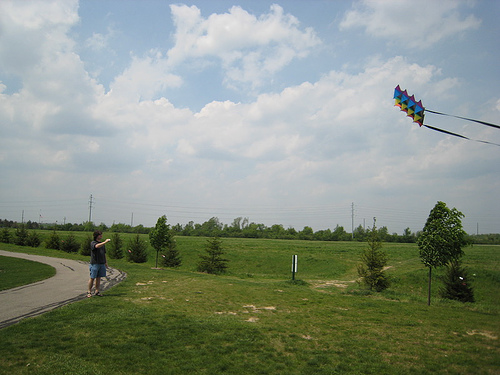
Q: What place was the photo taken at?
A: It was taken at the field.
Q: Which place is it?
A: It is a field.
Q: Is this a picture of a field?
A: Yes, it is showing a field.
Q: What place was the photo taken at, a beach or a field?
A: It was taken at a field.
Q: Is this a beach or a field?
A: It is a field.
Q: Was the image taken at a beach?
A: No, the picture was taken in a field.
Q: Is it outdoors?
A: Yes, it is outdoors.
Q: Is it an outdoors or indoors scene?
A: It is outdoors.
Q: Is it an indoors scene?
A: No, it is outdoors.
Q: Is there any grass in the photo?
A: Yes, there is grass.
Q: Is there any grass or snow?
A: Yes, there is grass.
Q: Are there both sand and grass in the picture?
A: No, there is grass but no sand.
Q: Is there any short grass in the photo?
A: Yes, there is short grass.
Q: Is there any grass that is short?
A: Yes, there is grass that is short.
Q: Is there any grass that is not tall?
A: Yes, there is short grass.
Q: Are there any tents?
A: No, there are no tents.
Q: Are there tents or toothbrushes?
A: No, there are no tents or toothbrushes.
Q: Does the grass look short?
A: Yes, the grass is short.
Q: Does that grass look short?
A: Yes, the grass is short.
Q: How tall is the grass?
A: The grass is short.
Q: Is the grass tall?
A: No, the grass is short.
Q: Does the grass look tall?
A: No, the grass is short.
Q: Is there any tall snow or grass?
A: No, there is grass but it is short.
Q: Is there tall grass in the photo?
A: No, there is grass but it is short.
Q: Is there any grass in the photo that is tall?
A: No, there is grass but it is short.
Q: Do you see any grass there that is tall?
A: No, there is grass but it is short.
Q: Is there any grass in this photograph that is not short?
A: No, there is grass but it is short.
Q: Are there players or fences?
A: No, there are no fences or players.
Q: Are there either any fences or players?
A: No, there are no fences or players.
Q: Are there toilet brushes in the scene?
A: No, there are no toilet brushes.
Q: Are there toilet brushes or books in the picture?
A: No, there are no toilet brushes or books.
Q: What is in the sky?
A: The clouds are in the sky.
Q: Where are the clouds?
A: The clouds are in the sky.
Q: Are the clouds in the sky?
A: Yes, the clouds are in the sky.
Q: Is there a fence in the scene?
A: No, there are no fences.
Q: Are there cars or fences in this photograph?
A: No, there are no fences or cars.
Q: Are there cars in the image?
A: No, there are no cars.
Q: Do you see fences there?
A: No, there are no fences.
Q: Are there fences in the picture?
A: No, there are no fences.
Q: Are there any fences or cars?
A: No, there are no fences or cars.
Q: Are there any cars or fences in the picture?
A: No, there are no fences or cars.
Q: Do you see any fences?
A: No, there are no fences.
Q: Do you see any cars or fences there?
A: No, there are no fences or cars.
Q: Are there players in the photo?
A: No, there are no players.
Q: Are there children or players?
A: No, there are no players or children.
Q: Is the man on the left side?
A: Yes, the man is on the left of the image.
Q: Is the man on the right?
A: No, the man is on the left of the image.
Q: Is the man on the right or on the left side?
A: The man is on the left of the image.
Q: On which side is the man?
A: The man is on the left of the image.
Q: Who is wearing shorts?
A: The man is wearing shorts.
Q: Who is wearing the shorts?
A: The man is wearing shorts.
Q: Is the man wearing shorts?
A: Yes, the man is wearing shorts.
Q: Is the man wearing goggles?
A: No, the man is wearing shorts.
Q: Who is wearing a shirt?
A: The man is wearing a shirt.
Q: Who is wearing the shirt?
A: The man is wearing a shirt.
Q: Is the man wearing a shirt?
A: Yes, the man is wearing a shirt.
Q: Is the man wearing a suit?
A: No, the man is wearing a shirt.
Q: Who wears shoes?
A: The man wears shoes.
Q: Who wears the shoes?
A: The man wears shoes.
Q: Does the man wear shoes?
A: Yes, the man wears shoes.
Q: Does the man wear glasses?
A: No, the man wears shoes.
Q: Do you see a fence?
A: No, there are no fences.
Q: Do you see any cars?
A: No, there are no cars.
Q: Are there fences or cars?
A: No, there are no cars or fences.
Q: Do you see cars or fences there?
A: No, there are no cars or fences.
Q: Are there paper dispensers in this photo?
A: No, there are no paper dispensers.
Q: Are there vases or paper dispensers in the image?
A: No, there are no paper dispensers or vases.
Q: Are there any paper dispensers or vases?
A: No, there are no paper dispensers or vases.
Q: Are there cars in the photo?
A: No, there are no cars.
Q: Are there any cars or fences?
A: No, there are no cars or fences.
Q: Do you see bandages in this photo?
A: No, there are no bandages.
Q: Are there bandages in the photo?
A: No, there are no bandages.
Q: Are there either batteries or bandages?
A: No, there are no bandages or batteries.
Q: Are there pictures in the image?
A: No, there are no pictures.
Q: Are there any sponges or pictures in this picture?
A: No, there are no pictures or sponges.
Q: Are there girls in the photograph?
A: No, there are no girls.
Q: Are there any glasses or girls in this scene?
A: No, there are no girls or glasses.